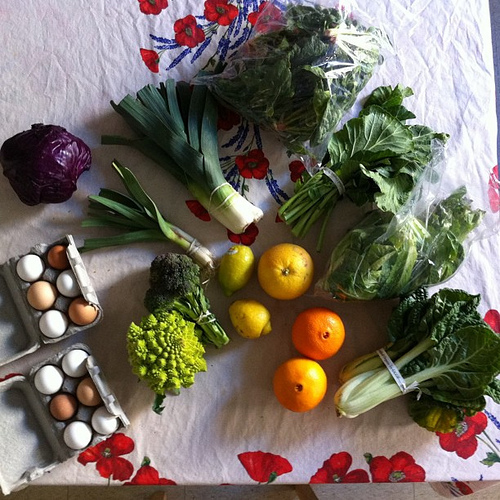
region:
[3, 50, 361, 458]
Food laid out on table.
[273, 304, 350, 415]
Navel oranges lying on table.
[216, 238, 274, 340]
Lemons lying on table.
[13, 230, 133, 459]
Eggs in carton on table.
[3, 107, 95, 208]
Purple cabbage lying on table.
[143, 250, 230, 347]
Broccoli stalk lying on table.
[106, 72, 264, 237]
Green onion lying on table.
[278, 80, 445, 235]
Collard greens lying on table.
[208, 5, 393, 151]
Swiss chard in bag lying on table.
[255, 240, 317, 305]
Grapefruit lying on table.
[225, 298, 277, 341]
a lemon w/ just a speck of bumpiness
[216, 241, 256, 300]
a long lemon or lime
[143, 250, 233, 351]
an ordinary bunch of broccoli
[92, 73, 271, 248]
a bunch of leeks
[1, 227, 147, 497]
two six packs of multi-color eggs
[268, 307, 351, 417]
two navel oranges, round navels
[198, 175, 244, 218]
rubber band around leeks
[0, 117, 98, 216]
red cabbage or radicchio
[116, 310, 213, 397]
romanesco--fibonacci--broccoli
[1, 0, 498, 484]
old wrinkled cotton tablecloth covered in poppies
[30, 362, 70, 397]
egg in a carton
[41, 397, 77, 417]
egg in a carton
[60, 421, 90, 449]
egg in a carton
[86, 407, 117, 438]
egg in a carton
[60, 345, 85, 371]
egg in a carton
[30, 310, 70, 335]
egg in a carton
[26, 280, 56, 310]
egg in a carton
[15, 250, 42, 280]
egg in a carton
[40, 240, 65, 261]
egg in a carton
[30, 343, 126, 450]
carton of brown and white eggs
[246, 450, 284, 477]
flower pattern on tablecloth.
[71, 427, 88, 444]
white egg in carton.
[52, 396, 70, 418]
brown egg in carton.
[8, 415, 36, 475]
top of egg carton.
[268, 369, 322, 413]
orange on the table.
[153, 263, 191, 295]
broccoli on the table.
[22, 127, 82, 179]
cabbage on the table.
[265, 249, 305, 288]
lemon on the table.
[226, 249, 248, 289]
lime on the table.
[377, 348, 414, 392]
wrap around the vegetable.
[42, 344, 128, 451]
brown and white eggs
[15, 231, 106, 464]
Two cartons of eggs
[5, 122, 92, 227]
A large red cabbage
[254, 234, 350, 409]
there are three oranges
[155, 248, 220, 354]
A large stem of broccoli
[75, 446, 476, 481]
The cloth has flowers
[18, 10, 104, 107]
The cloth is white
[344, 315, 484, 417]
The vegetable is green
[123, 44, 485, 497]
Vegetables on the table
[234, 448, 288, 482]
The flowers are red